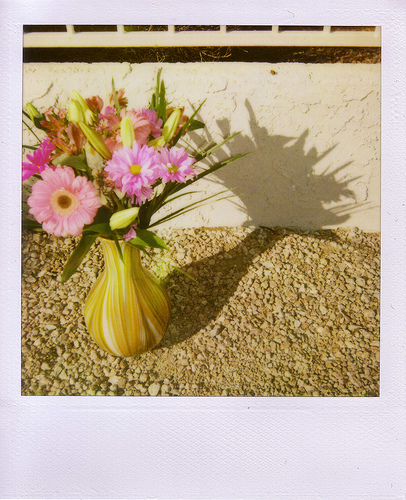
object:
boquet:
[21, 66, 252, 293]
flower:
[104, 140, 162, 198]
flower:
[21, 136, 57, 183]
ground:
[297, 139, 327, 204]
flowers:
[22, 67, 253, 282]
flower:
[21, 66, 255, 286]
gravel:
[22, 224, 382, 396]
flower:
[154, 144, 201, 184]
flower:
[132, 106, 163, 138]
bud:
[78, 119, 112, 160]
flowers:
[26, 139, 199, 239]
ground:
[21, 220, 379, 403]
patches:
[82, 235, 171, 358]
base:
[82, 235, 171, 357]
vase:
[80, 227, 172, 356]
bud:
[120, 115, 135, 148]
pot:
[84, 229, 170, 357]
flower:
[27, 163, 103, 237]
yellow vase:
[83, 235, 172, 358]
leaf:
[60, 221, 101, 285]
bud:
[109, 206, 141, 230]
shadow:
[149, 98, 379, 352]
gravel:
[262, 286, 353, 371]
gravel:
[200, 257, 324, 369]